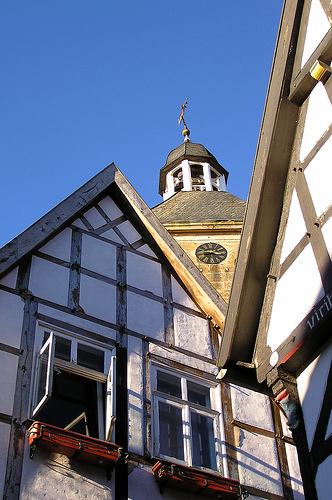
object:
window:
[28, 316, 117, 455]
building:
[0, 160, 306, 500]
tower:
[150, 98, 248, 230]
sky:
[46, 32, 147, 99]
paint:
[282, 339, 304, 364]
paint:
[244, 223, 253, 263]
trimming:
[282, 336, 305, 366]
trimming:
[214, 260, 248, 366]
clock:
[195, 241, 228, 265]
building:
[147, 95, 249, 311]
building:
[216, 0, 332, 500]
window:
[146, 357, 229, 482]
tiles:
[233, 423, 284, 499]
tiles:
[125, 250, 163, 299]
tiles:
[80, 232, 116, 281]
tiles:
[28, 255, 70, 309]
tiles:
[266, 242, 326, 355]